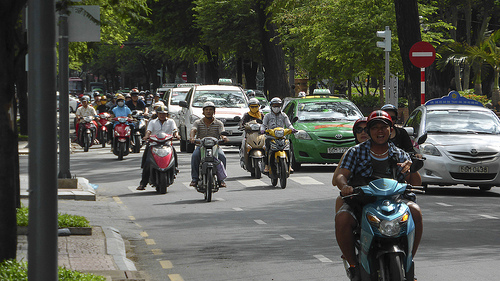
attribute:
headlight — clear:
[378, 219, 400, 236]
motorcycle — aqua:
[339, 179, 425, 279]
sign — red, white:
[408, 40, 437, 68]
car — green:
[282, 93, 365, 169]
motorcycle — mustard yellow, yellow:
[261, 124, 298, 188]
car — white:
[403, 102, 499, 190]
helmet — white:
[269, 96, 284, 110]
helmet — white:
[200, 100, 216, 110]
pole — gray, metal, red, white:
[383, 51, 391, 105]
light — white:
[375, 24, 394, 54]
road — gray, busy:
[69, 114, 497, 279]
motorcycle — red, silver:
[141, 132, 179, 195]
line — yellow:
[109, 196, 186, 279]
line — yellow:
[180, 177, 332, 266]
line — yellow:
[433, 201, 497, 220]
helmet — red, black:
[367, 109, 394, 125]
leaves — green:
[67, 1, 455, 81]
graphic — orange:
[312, 121, 351, 133]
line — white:
[410, 51, 434, 57]